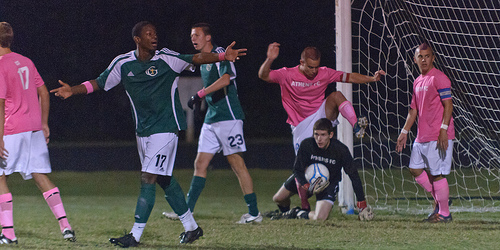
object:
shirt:
[406, 67, 456, 144]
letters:
[327, 159, 335, 166]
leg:
[322, 88, 358, 126]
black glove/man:
[183, 95, 205, 110]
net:
[348, 1, 500, 213]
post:
[332, 0, 357, 212]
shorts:
[133, 132, 178, 177]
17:
[153, 153, 167, 169]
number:
[233, 132, 245, 146]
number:
[19, 65, 32, 91]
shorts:
[196, 117, 247, 157]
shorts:
[289, 99, 340, 156]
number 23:
[226, 132, 245, 149]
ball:
[303, 162, 330, 189]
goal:
[332, 0, 499, 214]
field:
[0, 166, 499, 250]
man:
[393, 42, 458, 224]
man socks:
[0, 191, 15, 238]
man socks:
[426, 176, 449, 221]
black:
[329, 147, 347, 156]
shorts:
[0, 130, 52, 181]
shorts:
[404, 138, 455, 175]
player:
[160, 22, 265, 226]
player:
[0, 21, 74, 242]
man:
[260, 118, 367, 223]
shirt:
[290, 136, 365, 203]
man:
[50, 20, 248, 248]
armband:
[81, 80, 94, 94]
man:
[256, 41, 387, 211]